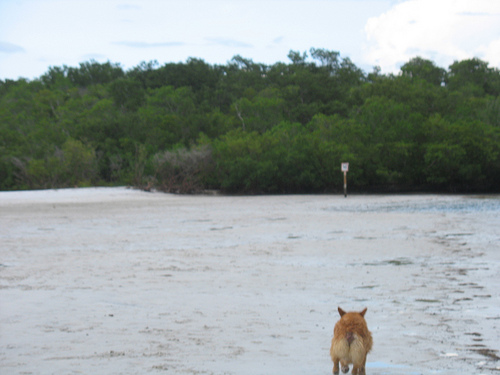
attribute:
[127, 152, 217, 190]
limbs — dead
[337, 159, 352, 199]
sign — white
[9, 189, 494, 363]
beach — sandy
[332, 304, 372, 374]
fox — running, red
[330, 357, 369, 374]
legs — four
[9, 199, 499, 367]
waves — water waves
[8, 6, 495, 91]
sky — hazy, light blue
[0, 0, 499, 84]
sky — cloudy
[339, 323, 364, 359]
fur — brown, white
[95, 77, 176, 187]
tree — green, leafy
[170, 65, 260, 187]
tree — green, leafy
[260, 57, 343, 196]
tree — green, leafy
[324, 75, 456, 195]
tree — green, leafy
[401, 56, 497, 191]
tree — green, leafy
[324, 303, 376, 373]
dog — small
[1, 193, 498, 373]
water — faded